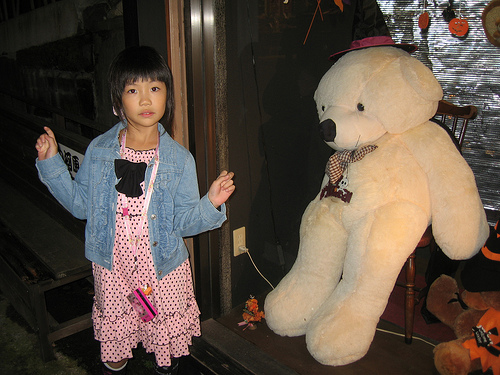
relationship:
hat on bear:
[329, 35, 417, 64] [300, 15, 453, 353]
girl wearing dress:
[29, 32, 241, 373] [90, 130, 208, 367]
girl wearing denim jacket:
[29, 32, 241, 373] [32, 115, 235, 280]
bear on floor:
[266, 35, 490, 366] [273, 316, 477, 353]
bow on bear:
[324, 142, 377, 185] [266, 43, 479, 373]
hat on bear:
[329, 35, 417, 64] [266, 43, 479, 373]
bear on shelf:
[266, 43, 479, 373] [187, 294, 491, 373]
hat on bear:
[329, 0, 431, 46] [266, 35, 490, 366]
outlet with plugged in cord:
[231, 224, 246, 258] [239, 246, 436, 351]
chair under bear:
[46, 66, 101, 130] [266, 35, 490, 366]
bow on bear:
[324, 142, 377, 185] [266, 35, 490, 366]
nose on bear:
[317, 117, 337, 147] [266, 35, 490, 366]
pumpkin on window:
[414, 1, 474, 43] [381, 5, 498, 138]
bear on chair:
[266, 35, 490, 366] [393, 226, 447, 356]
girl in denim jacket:
[37, 44, 235, 375] [34, 119, 228, 280]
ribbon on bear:
[260, 45, 495, 363] [317, 144, 386, 184]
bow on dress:
[113, 155, 148, 197] [90, 130, 208, 367]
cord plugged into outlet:
[233, 244, 440, 358] [228, 217, 249, 257]